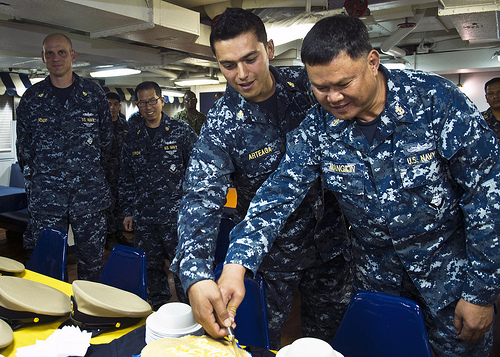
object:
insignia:
[394, 104, 405, 115]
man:
[117, 81, 199, 312]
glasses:
[135, 97, 163, 109]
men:
[217, 14, 499, 356]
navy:
[16, 32, 114, 280]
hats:
[58, 278, 153, 337]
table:
[0, 269, 346, 356]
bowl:
[143, 302, 203, 336]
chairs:
[329, 291, 431, 356]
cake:
[141, 333, 252, 356]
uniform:
[221, 64, 499, 356]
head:
[133, 80, 163, 120]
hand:
[123, 214, 135, 232]